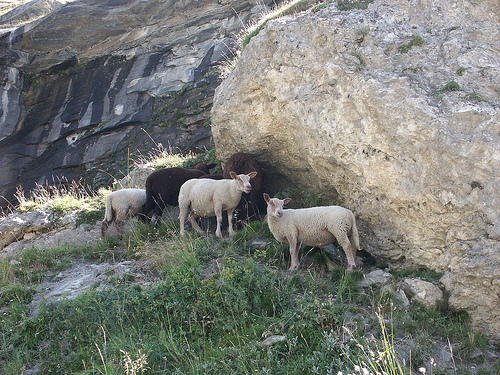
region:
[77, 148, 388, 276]
Sheep grazing on a hillside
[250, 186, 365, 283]
White sheep looking for danger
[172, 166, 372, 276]
Two white sheep grazing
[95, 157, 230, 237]
One black sheep with two white sheep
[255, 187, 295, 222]
Head of white sheep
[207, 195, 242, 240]
Front legs of white sheep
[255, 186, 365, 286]
White sheep with head turned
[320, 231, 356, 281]
Hind legs of white sheep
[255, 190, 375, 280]
White sheep alert for predators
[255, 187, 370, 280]
Female white sheep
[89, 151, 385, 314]
four animals are present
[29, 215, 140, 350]
rocks are present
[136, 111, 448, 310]
brown and white animals are present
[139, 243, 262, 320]
grass is green and yellow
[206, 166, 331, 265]
four ears are present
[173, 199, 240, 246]
four legs are present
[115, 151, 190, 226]
these animals are facing away from the camera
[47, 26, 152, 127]
big black rock is present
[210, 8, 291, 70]
sun is shining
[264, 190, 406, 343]
animal is looking to the right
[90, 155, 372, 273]
Five sheeps near huge rock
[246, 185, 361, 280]
white sheep turn his neck to the right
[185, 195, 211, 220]
belly of sheep is bulky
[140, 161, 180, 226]
back part of a black sheep can be seen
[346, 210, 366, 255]
tail of sheep is long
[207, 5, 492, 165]
a big rock on a mountain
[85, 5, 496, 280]
sheeps are on the shaded part of the mountain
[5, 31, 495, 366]
sheeps are in a rocky mountain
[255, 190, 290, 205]
ears of sheep are long and pointy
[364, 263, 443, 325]
small rocks next to big rock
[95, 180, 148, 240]
White sheep in back of flock of sheep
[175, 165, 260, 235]
White sheep second from front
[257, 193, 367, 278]
Front sheep of flock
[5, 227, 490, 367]
Grass on mountain side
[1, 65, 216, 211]
Black rock formation in back of sheep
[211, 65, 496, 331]
Light colored rock formation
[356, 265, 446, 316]
Small rock on grass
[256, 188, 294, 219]
Head of first sheep in flock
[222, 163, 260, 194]
Second sheep's head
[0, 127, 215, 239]
Sunlight beaming on ground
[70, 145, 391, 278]
a group of sheep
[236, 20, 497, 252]
A large boulder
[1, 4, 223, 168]
the face of a cliff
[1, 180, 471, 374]
a rocky hioll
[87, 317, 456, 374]
some wild mountain flowers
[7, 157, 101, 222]
some wild mountain flowers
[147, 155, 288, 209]
A pair of black sheep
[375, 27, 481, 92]
moss growing on the boulder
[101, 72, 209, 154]
moss growing on the cliff face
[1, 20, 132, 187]
water on the cliff face